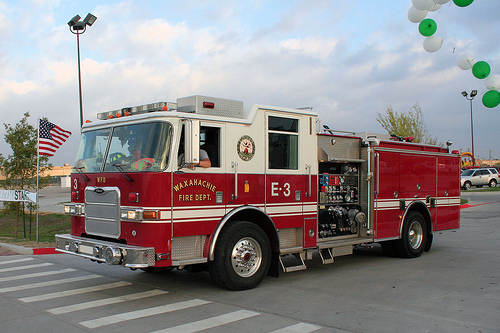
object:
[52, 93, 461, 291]
firetruck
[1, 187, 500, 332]
street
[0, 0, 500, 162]
sky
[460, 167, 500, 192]
suv